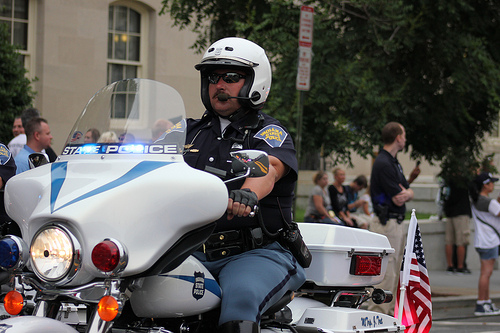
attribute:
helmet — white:
[194, 36, 271, 107]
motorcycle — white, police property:
[4, 76, 407, 331]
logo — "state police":
[59, 145, 180, 155]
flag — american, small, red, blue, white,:
[395, 205, 433, 332]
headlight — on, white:
[27, 221, 82, 285]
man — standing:
[370, 120, 414, 329]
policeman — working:
[141, 38, 311, 332]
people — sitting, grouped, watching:
[308, 168, 376, 230]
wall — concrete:
[400, 218, 499, 267]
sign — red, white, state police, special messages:
[298, 5, 312, 92]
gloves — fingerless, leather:
[227, 187, 259, 212]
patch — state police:
[253, 123, 287, 148]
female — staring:
[470, 172, 500, 314]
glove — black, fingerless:
[225, 188, 258, 213]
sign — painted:
[58, 142, 179, 155]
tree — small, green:
[1, 25, 43, 145]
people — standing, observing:
[11, 116, 134, 176]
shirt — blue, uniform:
[148, 110, 297, 235]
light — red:
[89, 238, 121, 273]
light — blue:
[0, 236, 20, 268]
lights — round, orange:
[1, 291, 119, 320]